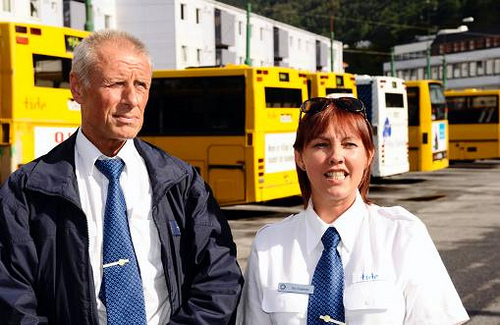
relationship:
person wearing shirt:
[236, 97, 473, 325] [247, 198, 469, 323]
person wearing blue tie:
[240, 95, 480, 323] [305, 225, 349, 324]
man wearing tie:
[0, 27, 245, 324] [89, 156, 156, 323]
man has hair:
[53, 27, 178, 203] [68, 42, 93, 72]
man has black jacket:
[0, 27, 245, 324] [0, 30, 247, 322]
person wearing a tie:
[236, 97, 473, 325] [304, 226, 348, 319]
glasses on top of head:
[297, 96, 369, 118] [55, 33, 162, 146]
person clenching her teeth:
[236, 97, 473, 325] [322, 170, 346, 181]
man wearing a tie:
[0, 27, 245, 324] [89, 156, 156, 323]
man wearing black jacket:
[0, 27, 245, 324] [0, 126, 247, 324]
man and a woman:
[0, 27, 245, 324] [250, 95, 467, 320]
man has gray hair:
[0, 27, 245, 324] [69, 30, 154, 92]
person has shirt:
[236, 97, 473, 325] [235, 188, 471, 324]